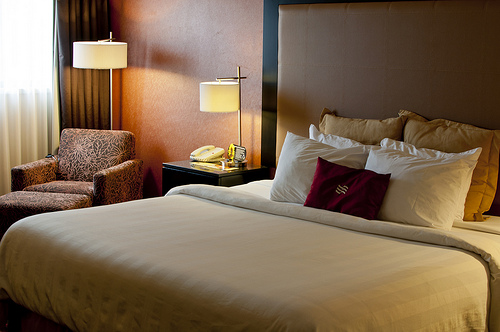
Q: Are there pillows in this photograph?
A: Yes, there is a pillow.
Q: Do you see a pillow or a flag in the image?
A: Yes, there is a pillow.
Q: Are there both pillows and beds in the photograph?
A: Yes, there are both a pillow and a bed.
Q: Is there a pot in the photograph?
A: No, there are no pots.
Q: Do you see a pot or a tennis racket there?
A: No, there are no pots or rackets.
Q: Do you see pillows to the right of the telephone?
A: Yes, there is a pillow to the right of the telephone.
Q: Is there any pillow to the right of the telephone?
A: Yes, there is a pillow to the right of the telephone.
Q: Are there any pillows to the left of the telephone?
A: No, the pillow is to the right of the telephone.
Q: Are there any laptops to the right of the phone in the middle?
A: No, there is a pillow to the right of the phone.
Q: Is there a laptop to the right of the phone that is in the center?
A: No, there is a pillow to the right of the phone.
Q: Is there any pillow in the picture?
A: Yes, there is a pillow.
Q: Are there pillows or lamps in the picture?
A: Yes, there is a pillow.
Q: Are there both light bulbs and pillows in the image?
A: No, there is a pillow but no light bulbs.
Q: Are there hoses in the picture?
A: No, there are no hoses.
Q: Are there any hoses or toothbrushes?
A: No, there are no hoses or toothbrushes.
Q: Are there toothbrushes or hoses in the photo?
A: No, there are no hoses or toothbrushes.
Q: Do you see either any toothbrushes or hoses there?
A: No, there are no hoses or toothbrushes.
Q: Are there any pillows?
A: Yes, there is a pillow.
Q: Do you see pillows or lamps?
A: Yes, there is a pillow.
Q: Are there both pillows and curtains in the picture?
A: Yes, there are both a pillow and a curtain.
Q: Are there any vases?
A: No, there are no vases.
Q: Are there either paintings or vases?
A: No, there are no vases or paintings.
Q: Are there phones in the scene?
A: Yes, there is a phone.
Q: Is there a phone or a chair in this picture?
A: Yes, there is a phone.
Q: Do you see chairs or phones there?
A: Yes, there is a phone.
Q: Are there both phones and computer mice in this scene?
A: No, there is a phone but no computer mice.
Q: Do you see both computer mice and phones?
A: No, there is a phone but no computer mice.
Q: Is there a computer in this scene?
A: No, there are no computers.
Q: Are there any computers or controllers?
A: No, there are no computers or controllers.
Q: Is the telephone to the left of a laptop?
A: No, the telephone is to the left of a pillow.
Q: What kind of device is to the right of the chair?
A: The device is a phone.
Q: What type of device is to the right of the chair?
A: The device is a phone.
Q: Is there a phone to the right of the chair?
A: Yes, there is a phone to the right of the chair.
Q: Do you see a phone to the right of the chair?
A: Yes, there is a phone to the right of the chair.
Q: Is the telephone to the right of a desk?
A: No, the telephone is to the right of a chair.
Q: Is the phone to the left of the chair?
A: No, the phone is to the right of the chair.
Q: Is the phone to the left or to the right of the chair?
A: The phone is to the right of the chair.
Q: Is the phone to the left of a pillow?
A: Yes, the phone is to the left of a pillow.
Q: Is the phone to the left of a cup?
A: No, the phone is to the left of a pillow.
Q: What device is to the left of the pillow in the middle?
A: The device is a phone.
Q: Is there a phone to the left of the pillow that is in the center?
A: Yes, there is a phone to the left of the pillow.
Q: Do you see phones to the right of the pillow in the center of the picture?
A: No, the phone is to the left of the pillow.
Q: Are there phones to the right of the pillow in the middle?
A: No, the phone is to the left of the pillow.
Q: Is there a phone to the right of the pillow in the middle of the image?
A: No, the phone is to the left of the pillow.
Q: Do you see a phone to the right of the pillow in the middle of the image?
A: No, the phone is to the left of the pillow.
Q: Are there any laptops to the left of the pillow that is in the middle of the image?
A: No, there is a phone to the left of the pillow.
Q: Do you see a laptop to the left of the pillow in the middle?
A: No, there is a phone to the left of the pillow.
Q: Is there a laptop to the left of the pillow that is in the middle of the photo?
A: No, there is a phone to the left of the pillow.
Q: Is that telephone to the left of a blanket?
A: No, the telephone is to the left of a pillow.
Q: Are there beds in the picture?
A: Yes, there is a bed.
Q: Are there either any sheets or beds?
A: Yes, there is a bed.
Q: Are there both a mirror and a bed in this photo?
A: No, there is a bed but no mirrors.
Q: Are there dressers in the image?
A: No, there are no dressers.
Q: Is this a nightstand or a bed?
A: This is a bed.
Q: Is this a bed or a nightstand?
A: This is a bed.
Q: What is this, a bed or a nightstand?
A: This is a bed.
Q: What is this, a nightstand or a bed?
A: This is a bed.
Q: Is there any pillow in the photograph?
A: Yes, there is a pillow.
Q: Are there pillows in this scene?
A: Yes, there is a pillow.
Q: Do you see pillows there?
A: Yes, there is a pillow.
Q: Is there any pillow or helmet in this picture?
A: Yes, there is a pillow.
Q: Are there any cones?
A: No, there are no cones.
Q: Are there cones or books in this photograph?
A: No, there are no cones or books.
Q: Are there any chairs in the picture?
A: Yes, there is a chair.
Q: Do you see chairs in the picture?
A: Yes, there is a chair.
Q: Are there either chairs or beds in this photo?
A: Yes, there is a chair.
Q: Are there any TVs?
A: No, there are no tvs.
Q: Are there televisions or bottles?
A: No, there are no televisions or bottles.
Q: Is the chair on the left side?
A: Yes, the chair is on the left of the image.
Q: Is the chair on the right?
A: No, the chair is on the left of the image.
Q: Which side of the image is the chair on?
A: The chair is on the left of the image.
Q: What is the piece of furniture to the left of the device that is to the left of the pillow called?
A: The piece of furniture is a chair.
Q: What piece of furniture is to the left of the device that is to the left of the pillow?
A: The piece of furniture is a chair.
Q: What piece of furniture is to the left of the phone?
A: The piece of furniture is a chair.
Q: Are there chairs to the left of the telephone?
A: Yes, there is a chair to the left of the telephone.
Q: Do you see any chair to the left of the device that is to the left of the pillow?
A: Yes, there is a chair to the left of the telephone.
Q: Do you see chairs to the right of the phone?
A: No, the chair is to the left of the phone.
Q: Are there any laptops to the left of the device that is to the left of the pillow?
A: No, there is a chair to the left of the telephone.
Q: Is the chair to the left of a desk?
A: No, the chair is to the left of the phone.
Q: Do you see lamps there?
A: Yes, there is a lamp.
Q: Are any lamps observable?
A: Yes, there is a lamp.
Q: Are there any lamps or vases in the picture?
A: Yes, there is a lamp.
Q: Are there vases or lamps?
A: Yes, there is a lamp.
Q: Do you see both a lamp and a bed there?
A: Yes, there are both a lamp and a bed.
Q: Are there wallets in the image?
A: No, there are no wallets.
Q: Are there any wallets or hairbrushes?
A: No, there are no wallets or hairbrushes.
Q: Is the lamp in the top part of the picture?
A: Yes, the lamp is in the top of the image.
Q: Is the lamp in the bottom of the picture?
A: No, the lamp is in the top of the image.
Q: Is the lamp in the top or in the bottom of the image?
A: The lamp is in the top of the image.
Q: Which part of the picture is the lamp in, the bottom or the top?
A: The lamp is in the top of the image.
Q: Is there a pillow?
A: Yes, there is a pillow.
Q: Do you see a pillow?
A: Yes, there is a pillow.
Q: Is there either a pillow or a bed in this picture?
A: Yes, there is a pillow.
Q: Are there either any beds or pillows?
A: Yes, there is a pillow.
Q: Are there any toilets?
A: No, there are no toilets.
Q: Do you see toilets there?
A: No, there are no toilets.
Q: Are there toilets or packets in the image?
A: No, there are no toilets or packets.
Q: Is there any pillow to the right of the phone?
A: Yes, there is a pillow to the right of the phone.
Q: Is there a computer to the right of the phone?
A: No, there is a pillow to the right of the phone.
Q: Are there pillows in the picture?
A: Yes, there is a pillow.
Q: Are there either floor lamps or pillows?
A: Yes, there is a pillow.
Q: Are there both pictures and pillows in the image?
A: No, there is a pillow but no pictures.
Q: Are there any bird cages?
A: No, there are no bird cages.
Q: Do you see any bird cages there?
A: No, there are no bird cages.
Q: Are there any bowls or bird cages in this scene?
A: No, there are no bird cages or bowls.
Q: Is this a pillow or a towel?
A: This is a pillow.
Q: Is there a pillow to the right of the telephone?
A: Yes, there is a pillow to the right of the telephone.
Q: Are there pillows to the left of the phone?
A: No, the pillow is to the right of the phone.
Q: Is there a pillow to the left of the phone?
A: No, the pillow is to the right of the phone.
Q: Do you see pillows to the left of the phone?
A: No, the pillow is to the right of the phone.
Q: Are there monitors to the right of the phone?
A: No, there is a pillow to the right of the phone.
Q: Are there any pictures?
A: No, there are no pictures.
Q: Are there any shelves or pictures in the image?
A: No, there are no pictures or shelves.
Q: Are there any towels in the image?
A: No, there are no towels.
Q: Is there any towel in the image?
A: No, there are no towels.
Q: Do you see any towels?
A: No, there are no towels.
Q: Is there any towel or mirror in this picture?
A: No, there are no towels or mirrors.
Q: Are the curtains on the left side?
A: Yes, the curtains are on the left of the image.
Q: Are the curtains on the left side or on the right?
A: The curtains are on the left of the image.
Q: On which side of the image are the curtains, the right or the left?
A: The curtains are on the left of the image.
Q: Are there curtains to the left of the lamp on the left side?
A: Yes, there are curtains to the left of the lamp.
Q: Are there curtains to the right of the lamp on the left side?
A: No, the curtains are to the left of the lamp.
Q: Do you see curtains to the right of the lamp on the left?
A: No, the curtains are to the left of the lamp.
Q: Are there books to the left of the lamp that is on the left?
A: No, there are curtains to the left of the lamp.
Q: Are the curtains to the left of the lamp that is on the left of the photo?
A: Yes, the curtains are to the left of the lamp.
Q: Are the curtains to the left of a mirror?
A: No, the curtains are to the left of the lamp.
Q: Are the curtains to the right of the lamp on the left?
A: No, the curtains are to the left of the lamp.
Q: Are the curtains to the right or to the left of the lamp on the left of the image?
A: The curtains are to the left of the lamp.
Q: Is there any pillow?
A: Yes, there is a pillow.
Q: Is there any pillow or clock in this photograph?
A: Yes, there is a pillow.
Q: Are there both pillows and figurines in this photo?
A: No, there is a pillow but no figurines.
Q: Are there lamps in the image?
A: Yes, there is a lamp.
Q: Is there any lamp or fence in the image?
A: Yes, there is a lamp.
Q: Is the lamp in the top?
A: Yes, the lamp is in the top of the image.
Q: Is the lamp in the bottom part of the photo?
A: No, the lamp is in the top of the image.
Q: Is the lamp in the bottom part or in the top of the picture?
A: The lamp is in the top of the image.